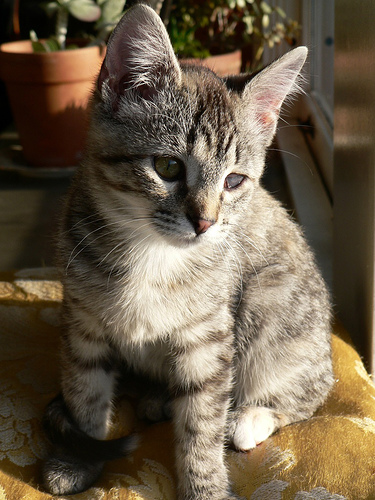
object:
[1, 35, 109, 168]
clay pot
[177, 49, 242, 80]
clay pot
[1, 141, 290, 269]
table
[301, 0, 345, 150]
sky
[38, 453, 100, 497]
paw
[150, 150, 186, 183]
eye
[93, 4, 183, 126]
ear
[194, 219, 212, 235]
nose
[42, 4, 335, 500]
cat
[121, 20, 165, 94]
furry ears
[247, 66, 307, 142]
furry ears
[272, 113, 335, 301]
sill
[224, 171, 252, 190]
eye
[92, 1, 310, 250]
head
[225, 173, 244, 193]
eye socket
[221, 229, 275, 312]
whisker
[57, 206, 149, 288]
whisker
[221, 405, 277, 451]
paw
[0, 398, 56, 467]
flower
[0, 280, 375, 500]
yellow pillow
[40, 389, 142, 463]
tail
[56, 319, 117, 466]
lag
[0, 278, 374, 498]
blanket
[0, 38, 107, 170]
flower pot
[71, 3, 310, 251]
plane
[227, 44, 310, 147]
ears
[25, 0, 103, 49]
plant